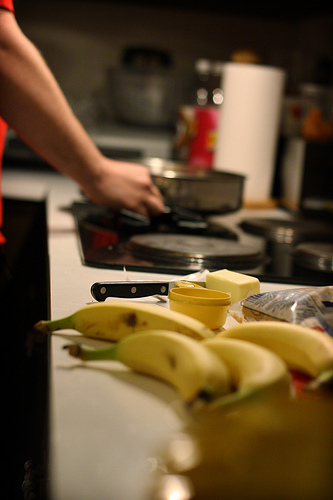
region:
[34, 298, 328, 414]
four bananas on the kitchen counter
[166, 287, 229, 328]
yellow bowl next to the bananas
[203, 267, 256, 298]
stick of butter on the counter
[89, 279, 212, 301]
metal knife next to the butter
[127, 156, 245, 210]
shallow metal pan on the stove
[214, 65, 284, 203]
roll of paper towels on the counter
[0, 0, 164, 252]
person cooking on the stove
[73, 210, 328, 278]
black eletric stove in the kitchen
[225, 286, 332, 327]
plastic bag behind the bananas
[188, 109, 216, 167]
red and yellow can by the paper towels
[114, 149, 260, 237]
A pot on a stove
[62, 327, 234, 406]
A yellow banana laying on the counter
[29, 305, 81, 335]
A green banana stem on the counter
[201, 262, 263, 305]
A half a stick of butter on the counter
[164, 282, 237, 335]
A yellow round bowl on the counter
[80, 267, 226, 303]
A knife cutting through butter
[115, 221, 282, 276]
The burner of a stove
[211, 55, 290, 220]
A towel paper roll on a holder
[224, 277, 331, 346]
A bag of rice laying on the counter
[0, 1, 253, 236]
A mans hand grabbing a pot on a stove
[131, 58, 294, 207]
THE BACKGROUND IS BLURRY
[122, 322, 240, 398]
a group of bananas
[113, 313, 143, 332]
bruise on the banana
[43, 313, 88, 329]
stem of the banana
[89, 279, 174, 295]
handle on the knife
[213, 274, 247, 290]
a block of butter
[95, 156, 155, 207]
hand on the person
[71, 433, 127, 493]
the counter is gray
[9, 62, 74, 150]
arm of the person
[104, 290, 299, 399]
a bunch of bananas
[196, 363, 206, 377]
the banana is yellow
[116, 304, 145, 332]
bruise on the banana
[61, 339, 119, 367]
stem of the banana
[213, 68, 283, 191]
roll of paper towels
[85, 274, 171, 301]
handle of the knife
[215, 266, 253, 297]
the block of butter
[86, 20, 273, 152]
the background is blurry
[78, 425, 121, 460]
the counter is grey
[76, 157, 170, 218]
hand of the person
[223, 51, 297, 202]
a roll of paper towels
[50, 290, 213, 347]
a banana on a counter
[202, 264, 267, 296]
butter on a counter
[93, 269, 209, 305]
a knife with a black handle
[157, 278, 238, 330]
a small yellow bowl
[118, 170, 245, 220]
a metal pan on a stove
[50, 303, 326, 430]
four bananas on a counter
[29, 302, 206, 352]
a ripe yellow banana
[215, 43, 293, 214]
a roll of paper towels on a counter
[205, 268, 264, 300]
a butter quarter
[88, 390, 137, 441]
The table is white.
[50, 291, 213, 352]
The table has a banana.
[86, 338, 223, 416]
The table has another banana.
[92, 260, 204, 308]
A knife is on the table.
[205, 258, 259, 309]
Butter is on the table.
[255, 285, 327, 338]
A bag is on the table.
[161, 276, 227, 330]
A little cup is on the table.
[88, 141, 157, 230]
A hand is on the stove.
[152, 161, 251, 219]
A pot is on the stove.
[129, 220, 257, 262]
The stove is black.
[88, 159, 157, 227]
the hand of a person